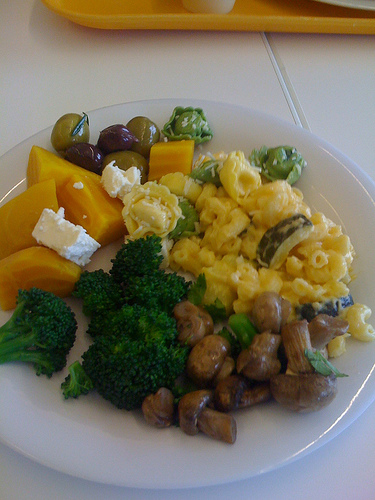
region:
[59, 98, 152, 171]
black and green olives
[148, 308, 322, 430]
sauteed muchrooms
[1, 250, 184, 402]
steamed green broccoli florets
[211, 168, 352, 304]
macaroni and cheese casserole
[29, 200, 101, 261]
unmelted pad of butter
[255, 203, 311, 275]
a peice of steamed zucchini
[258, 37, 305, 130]
Steamed chunks of winter squash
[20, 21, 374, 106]
white caulking on white tile table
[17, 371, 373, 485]
a white dinner plate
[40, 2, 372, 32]
edge of yellow tray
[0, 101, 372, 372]
a bunch of sweet items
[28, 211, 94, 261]
a white sweet item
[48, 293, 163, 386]
a beautiful green veges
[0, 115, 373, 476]
a plate containing food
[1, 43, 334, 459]
a round white plate having sweets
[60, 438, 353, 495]
a part of the plate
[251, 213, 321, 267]
a small decorative item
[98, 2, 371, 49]
a yellow part of the plate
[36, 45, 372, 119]
a beautiful white floor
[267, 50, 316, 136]
a small line in the floor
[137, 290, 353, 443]
the mushrooms are brown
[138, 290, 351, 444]
the mushrooms are on the plate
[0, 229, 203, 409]
the broccoli is green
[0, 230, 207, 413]
the broccoli is on the plate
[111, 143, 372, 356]
the mac and cheese is yellow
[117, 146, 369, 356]
the mac and cheese is on the plate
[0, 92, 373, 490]
the plate is white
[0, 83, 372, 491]
the plate is round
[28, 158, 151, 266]
the feta is on the plate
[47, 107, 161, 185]
the olives are on the plate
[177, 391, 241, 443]
brown mushroom on a white plate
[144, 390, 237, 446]
two pieces of mushroom on a white plate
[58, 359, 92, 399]
tiny piece of brocolli on a plate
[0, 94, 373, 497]
plate of food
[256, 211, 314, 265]
green vegetable on top of macaroni and cheese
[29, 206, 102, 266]
small piece of white crumbly cheese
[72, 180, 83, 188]
tiny crumb of cheese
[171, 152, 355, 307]
creamy macaroni and cheese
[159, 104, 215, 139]
green pasta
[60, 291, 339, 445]
mushrooms and brocolli on a white plate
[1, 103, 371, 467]
a colorful plate of food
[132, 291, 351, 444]
mushrooms on the plate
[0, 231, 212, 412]
broccoli on the plate of food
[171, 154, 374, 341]
a macaroni mixture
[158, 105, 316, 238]
what appears to be brussel sprouts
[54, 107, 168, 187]
a mixture of some olives of different colors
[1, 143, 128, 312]
some fruit on the plate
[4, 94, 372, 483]
the food is on a white plate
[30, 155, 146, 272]
white chunks of what may be cream cheese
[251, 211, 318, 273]
a chunk of some sort of vegetable